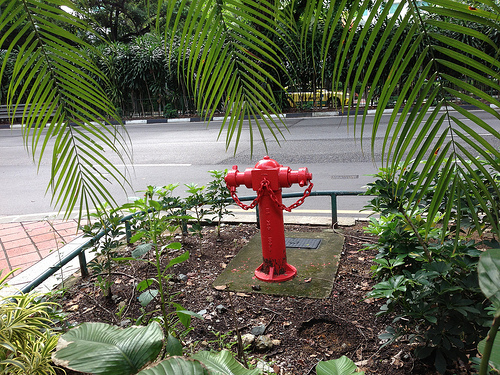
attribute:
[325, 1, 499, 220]
leaves — thin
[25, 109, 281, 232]
street — grey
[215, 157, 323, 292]
water hydrant — red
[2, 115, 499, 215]
road — tarmack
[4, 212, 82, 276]
blocks — brick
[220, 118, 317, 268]
hydrant — red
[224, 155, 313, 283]
hydrant — red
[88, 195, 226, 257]
rail — green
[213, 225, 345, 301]
block — concrete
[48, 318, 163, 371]
leaf — wide